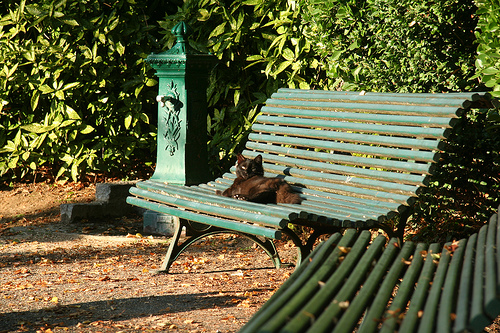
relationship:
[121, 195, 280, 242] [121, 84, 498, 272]
board on bench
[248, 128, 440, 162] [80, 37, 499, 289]
board on bench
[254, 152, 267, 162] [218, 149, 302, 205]
ear of cat